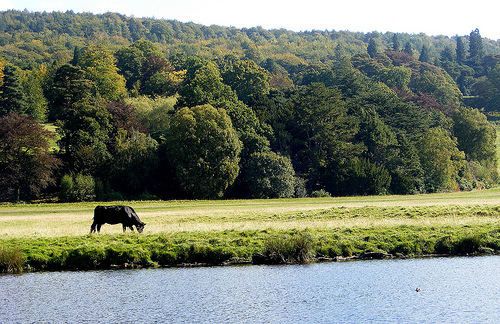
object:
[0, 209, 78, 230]
grass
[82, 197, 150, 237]
cow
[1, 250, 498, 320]
water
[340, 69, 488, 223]
trees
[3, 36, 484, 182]
forest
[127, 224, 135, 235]
legs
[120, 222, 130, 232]
legs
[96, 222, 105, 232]
legs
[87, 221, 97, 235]
legs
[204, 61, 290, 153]
leaves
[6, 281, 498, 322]
lake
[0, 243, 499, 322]
river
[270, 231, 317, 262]
bush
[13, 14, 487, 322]
no object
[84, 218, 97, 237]
hind leg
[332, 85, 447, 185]
trees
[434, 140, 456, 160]
leaves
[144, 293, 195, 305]
ripples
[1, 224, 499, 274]
shore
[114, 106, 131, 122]
leaves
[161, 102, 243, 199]
tree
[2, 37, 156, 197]
trees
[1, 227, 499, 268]
embankment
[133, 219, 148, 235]
head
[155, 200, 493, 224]
field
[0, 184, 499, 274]
ranch